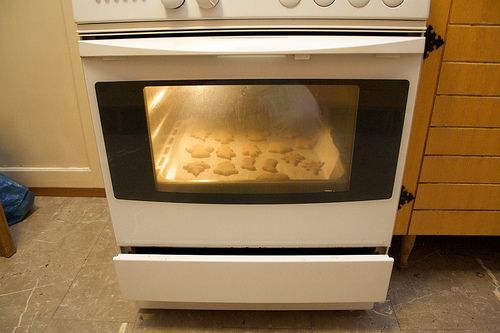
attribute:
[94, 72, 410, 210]
oven — white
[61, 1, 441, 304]
stove — black, white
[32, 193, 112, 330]
tile — square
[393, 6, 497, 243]
cabinets — wooded, small, on right, on left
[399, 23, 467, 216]
hinges — black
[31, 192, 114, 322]
floor — marble